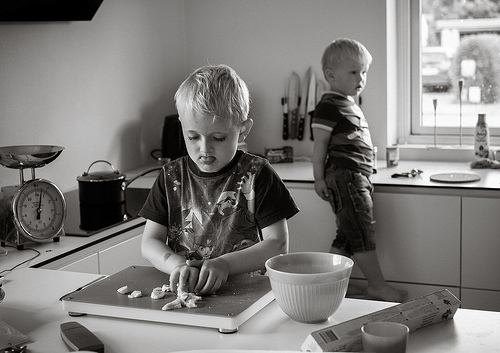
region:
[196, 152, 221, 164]
a boy sticking out his tongue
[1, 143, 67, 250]
a scale on a counter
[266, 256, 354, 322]
a bowl on the counter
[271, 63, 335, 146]
knives that are on a wall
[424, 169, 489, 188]
a plate on the counter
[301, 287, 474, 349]
a box of wax paper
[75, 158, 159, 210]
a pot on a stove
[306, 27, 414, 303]
a boy on a stool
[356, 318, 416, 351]
a white cup on counter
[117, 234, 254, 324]
a boy with some food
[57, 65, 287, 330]
child with hands curved on chopping board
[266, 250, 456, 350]
ceramic bowl next to long box and cup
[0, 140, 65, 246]
curved metal bowl over dial of weight scale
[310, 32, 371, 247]
child in dark clothes looking ahead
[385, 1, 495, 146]
window showing parked car next to hedges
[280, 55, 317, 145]
knives on wall with blades pointed up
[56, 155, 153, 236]
dark lidded pot on rectangular cooking surface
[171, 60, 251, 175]
boy looking down with tongue sticking out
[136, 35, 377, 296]
two boys in a kitchen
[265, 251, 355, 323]
light-colored ceramic bowl with ridged edges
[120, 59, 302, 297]
child standing in a kitchen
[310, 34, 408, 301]
child standing in a kitchen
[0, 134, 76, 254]
scale made out of silver metal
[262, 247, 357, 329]
large white bowl on the counter top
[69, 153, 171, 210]
black pot with a lid on it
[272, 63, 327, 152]
rack of knives hanging on a wall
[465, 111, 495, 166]
jar with a lid on it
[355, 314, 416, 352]
small cup on the counter top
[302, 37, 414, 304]
child wearing a pair of shorts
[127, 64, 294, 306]
child wearing a graphic tee shirt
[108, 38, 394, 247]
two boys in the room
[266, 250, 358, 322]
bowl on the counter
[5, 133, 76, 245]
scale on the counter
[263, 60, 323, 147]
knives on the wall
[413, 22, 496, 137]
window in the room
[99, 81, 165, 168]
shadow on the wall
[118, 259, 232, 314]
boy is picking up something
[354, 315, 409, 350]
cup on the counter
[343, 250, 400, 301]
boy is standing on a stool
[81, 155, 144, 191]
pot on the stove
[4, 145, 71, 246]
a scale on the counter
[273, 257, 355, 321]
a white bowl on the counter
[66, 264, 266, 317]
a cutting board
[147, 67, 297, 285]
a boy standing at the counter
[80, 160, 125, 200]
a pot on the stove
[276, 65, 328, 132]
knives hanging on the wall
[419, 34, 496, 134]
a window in the room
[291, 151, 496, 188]
the counter top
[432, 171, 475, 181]
a plate on the counter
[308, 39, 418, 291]
a young boy standing on a stool